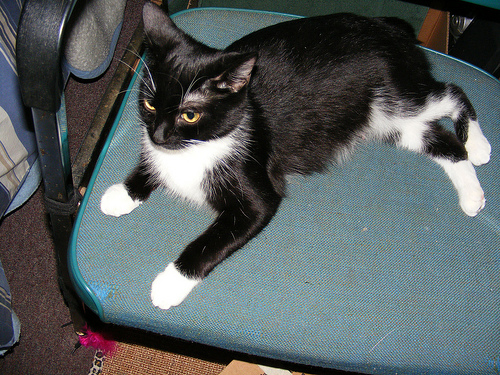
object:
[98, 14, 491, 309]
cat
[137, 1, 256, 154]
head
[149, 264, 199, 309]
paws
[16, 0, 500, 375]
seat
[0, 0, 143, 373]
carpet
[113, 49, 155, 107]
whiskers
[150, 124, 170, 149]
nose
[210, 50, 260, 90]
ears